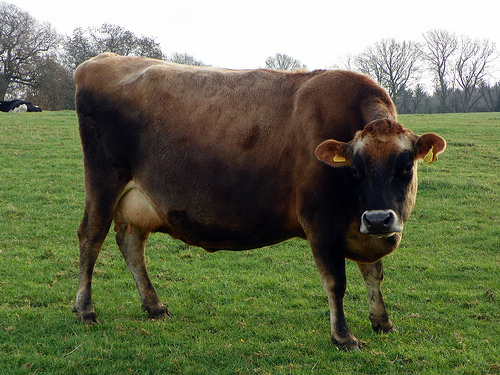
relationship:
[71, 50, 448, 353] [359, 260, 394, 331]
cow has leg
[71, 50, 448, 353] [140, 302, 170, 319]
cow has hoof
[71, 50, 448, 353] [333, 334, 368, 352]
cow has hoof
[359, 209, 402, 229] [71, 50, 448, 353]
nose on cow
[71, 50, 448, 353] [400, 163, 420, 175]
cow has cows eyes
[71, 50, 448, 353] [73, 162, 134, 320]
cow has a leg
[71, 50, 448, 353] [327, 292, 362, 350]
cow has foot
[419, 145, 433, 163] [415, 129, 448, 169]
tag on ear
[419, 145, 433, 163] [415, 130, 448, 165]
tag on cows ear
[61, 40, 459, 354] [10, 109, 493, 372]
cow in field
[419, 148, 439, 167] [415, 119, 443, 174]
tag hanging from cows ear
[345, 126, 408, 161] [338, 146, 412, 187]
spots above cows eyes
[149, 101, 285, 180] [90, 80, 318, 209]
spots on cows side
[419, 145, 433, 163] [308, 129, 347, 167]
tag inside cows ear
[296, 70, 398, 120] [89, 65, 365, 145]
hump on cows back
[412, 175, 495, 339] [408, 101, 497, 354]
grass in field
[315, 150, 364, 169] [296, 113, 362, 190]
tag in cows ear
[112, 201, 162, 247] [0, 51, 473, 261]
utters on a cow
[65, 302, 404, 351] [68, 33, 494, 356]
hooves of a cow